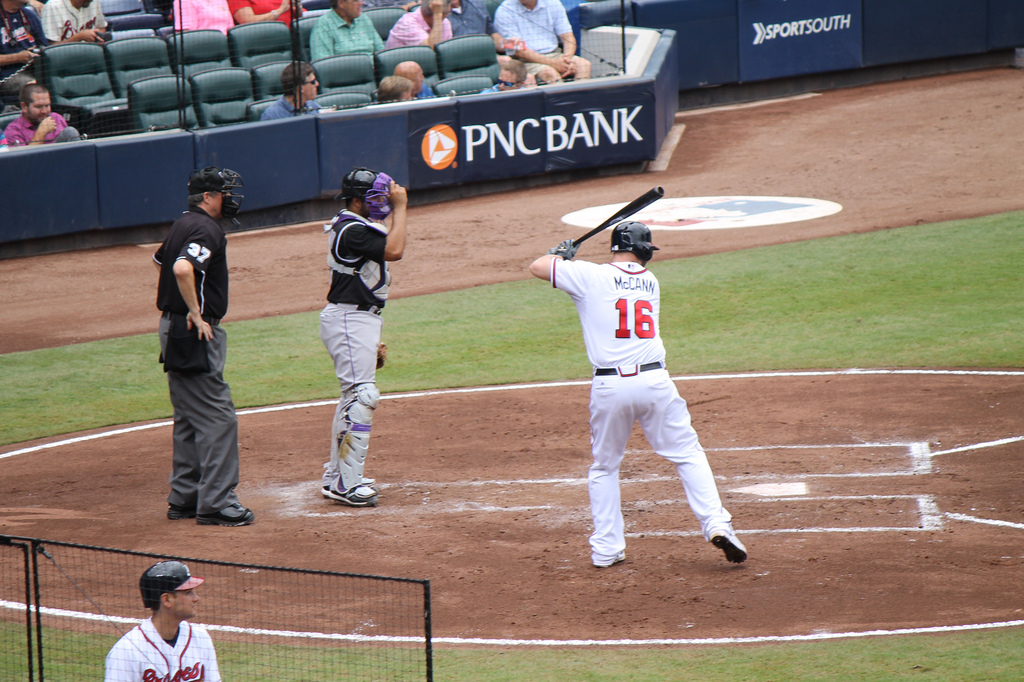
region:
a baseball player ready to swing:
[533, 168, 761, 586]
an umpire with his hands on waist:
[148, 162, 272, 537]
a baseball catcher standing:
[302, 160, 435, 534]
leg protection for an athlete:
[307, 380, 384, 518]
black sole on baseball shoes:
[702, 530, 753, 573]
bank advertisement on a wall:
[398, 91, 664, 190]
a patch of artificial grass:
[817, 272, 893, 337]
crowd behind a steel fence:
[312, 0, 619, 96]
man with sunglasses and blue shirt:
[262, 64, 339, 134]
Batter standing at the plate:
[529, 178, 749, 571]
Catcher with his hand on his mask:
[317, 162, 413, 510]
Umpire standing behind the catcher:
[151, 156, 257, 530]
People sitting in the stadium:
[1, 4, 596, 145]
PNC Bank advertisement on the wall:
[403, 75, 661, 200]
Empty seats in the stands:
[45, 19, 298, 125]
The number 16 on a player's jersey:
[615, 289, 657, 344]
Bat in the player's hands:
[557, 178, 669, 255]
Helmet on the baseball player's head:
[141, 554, 199, 599]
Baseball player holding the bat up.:
[528, 182, 747, 565]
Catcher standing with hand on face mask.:
[315, 163, 408, 499]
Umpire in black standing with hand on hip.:
[147, 160, 250, 519]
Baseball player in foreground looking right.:
[100, 555, 218, 673]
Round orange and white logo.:
[416, 118, 458, 169]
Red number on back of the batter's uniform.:
[610, 294, 655, 336]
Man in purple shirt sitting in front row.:
[0, 80, 81, 142]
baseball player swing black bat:
[509, 154, 766, 613]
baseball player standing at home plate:
[501, 151, 824, 597]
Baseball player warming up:
[503, 157, 827, 611]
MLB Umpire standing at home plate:
[124, 132, 314, 585]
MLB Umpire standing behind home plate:
[112, 143, 290, 545]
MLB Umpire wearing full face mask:
[124, 129, 284, 540]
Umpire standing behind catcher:
[106, 129, 315, 540]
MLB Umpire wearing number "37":
[125, 143, 285, 552]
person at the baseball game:
[263, 59, 318, 110]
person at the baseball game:
[4, 83, 78, 148]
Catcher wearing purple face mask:
[329, 150, 406, 226]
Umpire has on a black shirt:
[140, 156, 251, 333]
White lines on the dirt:
[0, 351, 1019, 649]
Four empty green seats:
[35, 10, 299, 94]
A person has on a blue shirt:
[257, 54, 335, 125]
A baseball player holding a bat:
[532, 160, 755, 571]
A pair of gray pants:
[141, 308, 250, 528]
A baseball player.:
[513, 175, 770, 591]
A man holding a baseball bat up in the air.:
[513, 181, 754, 577]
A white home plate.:
[722, 462, 811, 519]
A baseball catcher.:
[307, 119, 424, 515]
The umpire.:
[138, 184, 271, 542]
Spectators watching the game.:
[2, 2, 664, 157]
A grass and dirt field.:
[4, 84, 1011, 672]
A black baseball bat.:
[547, 179, 666, 244]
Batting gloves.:
[548, 231, 577, 258]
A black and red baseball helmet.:
[138, 556, 206, 613]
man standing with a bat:
[529, 182, 752, 566]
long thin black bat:
[551, 183, 666, 251]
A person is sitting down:
[271, 61, 338, 132]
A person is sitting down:
[391, 57, 434, 95]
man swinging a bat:
[520, 181, 755, 571]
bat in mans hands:
[565, 183, 668, 254]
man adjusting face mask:
[316, 161, 416, 509]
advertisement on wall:
[404, 83, 664, 191]